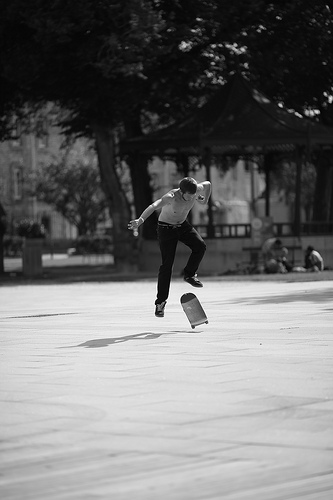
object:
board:
[179, 293, 208, 331]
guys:
[307, 244, 323, 271]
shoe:
[154, 297, 167, 319]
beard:
[182, 192, 188, 202]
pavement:
[0, 273, 333, 500]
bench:
[241, 244, 302, 272]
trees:
[0, 0, 168, 271]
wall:
[134, 227, 333, 274]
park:
[0, 0, 333, 499]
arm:
[139, 194, 172, 225]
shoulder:
[158, 188, 177, 207]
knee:
[197, 234, 208, 259]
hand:
[196, 194, 207, 206]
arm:
[195, 178, 213, 202]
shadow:
[55, 329, 203, 349]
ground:
[1, 267, 333, 500]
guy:
[125, 176, 213, 320]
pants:
[151, 219, 206, 303]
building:
[0, 58, 313, 238]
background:
[4, 0, 333, 271]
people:
[262, 237, 286, 271]